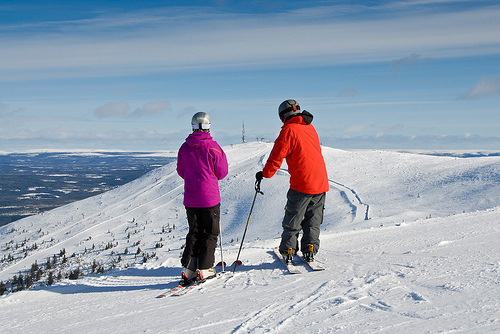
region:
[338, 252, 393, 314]
the snow is white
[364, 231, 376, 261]
the snow is white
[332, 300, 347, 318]
the snow is white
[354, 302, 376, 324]
the snow is white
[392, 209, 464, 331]
the snow is white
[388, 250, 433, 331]
the snow is white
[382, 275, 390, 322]
the snow is white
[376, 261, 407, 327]
the snow is white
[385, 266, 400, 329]
the snow is white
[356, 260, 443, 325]
the snow is white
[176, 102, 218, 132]
white cap of the person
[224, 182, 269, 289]
a long stick on ice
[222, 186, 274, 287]
skating stick holding by person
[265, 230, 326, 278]
a nice skatting machine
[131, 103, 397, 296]
two persons trying to skat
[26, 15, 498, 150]
a beautiful view of the sky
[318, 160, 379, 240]
a mark on ice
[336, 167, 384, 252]
previously skatted people mark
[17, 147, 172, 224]
beautiful view of town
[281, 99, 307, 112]
cap of the person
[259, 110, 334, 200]
the man is wearing a jacket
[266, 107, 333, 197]
the man's jacket is red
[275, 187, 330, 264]
the man is wearing pants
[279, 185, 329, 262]
the man's pants are grey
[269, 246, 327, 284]
the man is wearing skis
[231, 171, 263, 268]
the man is holding a ski pole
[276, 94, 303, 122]
the man is wearing a helmet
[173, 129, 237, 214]
the woman is wearing a jacket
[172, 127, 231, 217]
the woman's jacket is purple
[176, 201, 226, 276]
the woman is wearing black pants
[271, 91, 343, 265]
skier in red jacket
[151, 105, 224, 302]
skier in pink jacket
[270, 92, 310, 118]
safety helmet on skier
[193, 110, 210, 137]
safety helmet on skier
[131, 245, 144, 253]
evergreen tree down hill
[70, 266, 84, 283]
evergreen tree down hill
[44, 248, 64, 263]
evergreen tree down hill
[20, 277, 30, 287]
evergreen tree down hill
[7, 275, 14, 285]
evergreen tree down hill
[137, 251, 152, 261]
evergreen tree down hill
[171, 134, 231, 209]
the hoodie is pink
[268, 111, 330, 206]
the jacket is red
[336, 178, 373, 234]
the tracks are in the snow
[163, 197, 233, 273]
the pants are black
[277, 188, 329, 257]
the pants are gray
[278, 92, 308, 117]
the helmet is gray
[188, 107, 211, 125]
the helmet is shiney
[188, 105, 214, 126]
the helmet is silver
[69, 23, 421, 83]
the cloud goes across the sky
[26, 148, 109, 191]
the water is frozen